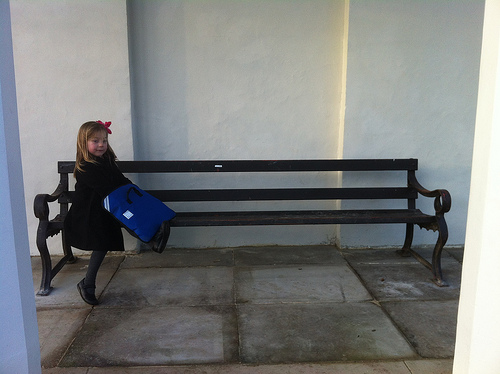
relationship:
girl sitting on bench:
[59, 120, 135, 305] [32, 159, 451, 297]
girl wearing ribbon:
[59, 120, 135, 305] [97, 118, 113, 134]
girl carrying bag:
[59, 120, 135, 305] [99, 180, 177, 253]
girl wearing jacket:
[59, 120, 135, 305] [61, 157, 131, 253]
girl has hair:
[59, 120, 135, 305] [72, 120, 118, 175]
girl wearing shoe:
[59, 120, 135, 305] [76, 276, 99, 305]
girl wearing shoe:
[59, 120, 135, 305] [149, 221, 169, 254]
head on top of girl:
[81, 122, 110, 157] [59, 120, 135, 305]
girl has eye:
[59, 120, 135, 305] [94, 140, 100, 144]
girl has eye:
[59, 120, 135, 305] [102, 138, 108, 142]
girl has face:
[59, 120, 135, 305] [90, 134, 108, 154]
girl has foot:
[59, 120, 135, 305] [75, 275, 101, 306]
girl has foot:
[59, 120, 135, 305] [149, 219, 172, 254]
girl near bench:
[59, 120, 135, 305] [32, 159, 451, 297]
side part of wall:
[8, 0, 148, 255] [9, 1, 488, 256]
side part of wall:
[336, 1, 486, 248] [9, 1, 488, 256]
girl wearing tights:
[59, 120, 135, 305] [83, 245, 106, 289]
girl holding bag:
[59, 120, 135, 305] [99, 180, 177, 253]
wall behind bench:
[9, 1, 488, 256] [32, 159, 451, 297]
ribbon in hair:
[97, 118, 113, 134] [72, 120, 118, 175]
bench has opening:
[32, 159, 451, 297] [47, 200, 62, 219]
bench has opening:
[32, 159, 451, 297] [415, 190, 438, 218]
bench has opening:
[32, 159, 451, 297] [68, 173, 77, 191]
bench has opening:
[32, 159, 451, 297] [122, 168, 410, 189]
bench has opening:
[32, 159, 451, 297] [161, 197, 411, 213]